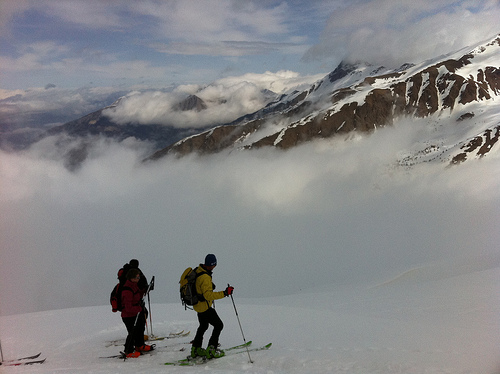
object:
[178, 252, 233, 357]
man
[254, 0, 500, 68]
sky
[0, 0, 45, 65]
clouds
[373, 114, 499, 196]
mountain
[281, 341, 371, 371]
tracks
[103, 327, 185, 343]
skis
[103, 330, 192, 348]
skis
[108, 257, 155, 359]
person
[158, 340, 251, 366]
skis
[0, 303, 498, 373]
snow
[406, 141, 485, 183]
snow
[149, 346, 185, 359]
skis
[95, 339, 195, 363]
skis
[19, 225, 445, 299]
snow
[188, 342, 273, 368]
skis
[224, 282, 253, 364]
ski pole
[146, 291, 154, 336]
ski pole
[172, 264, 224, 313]
coat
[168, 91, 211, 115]
mountians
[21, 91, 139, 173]
mountians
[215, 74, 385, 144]
snow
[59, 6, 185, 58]
sky